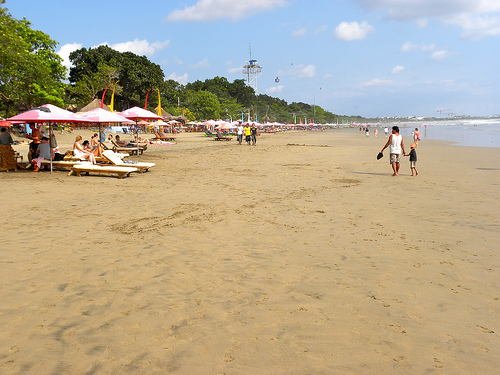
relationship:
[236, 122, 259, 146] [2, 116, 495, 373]
people walking on beach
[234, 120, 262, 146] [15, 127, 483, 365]
people walking along beach